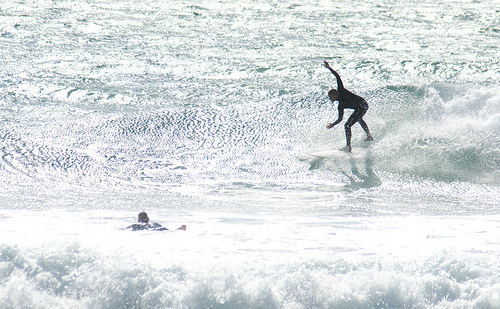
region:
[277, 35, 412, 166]
A person is surfing on water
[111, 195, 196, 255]
Another person is in the water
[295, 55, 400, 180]
Person is wearing a wetsuit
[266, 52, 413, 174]
Person's wetsuit is black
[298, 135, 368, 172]
Person's surfboard is white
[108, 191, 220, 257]
Person is laying flat on the water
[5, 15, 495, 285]
Picture was taken in the daytime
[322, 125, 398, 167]
Person on surfboard is barefoot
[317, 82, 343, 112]
Person on the surfboard has short hair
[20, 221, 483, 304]
The water is water in color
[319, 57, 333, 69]
the hand of a man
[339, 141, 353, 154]
the foot of a man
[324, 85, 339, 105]
the head of a man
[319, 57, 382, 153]
a man on a surfboard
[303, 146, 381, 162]
a white surfboard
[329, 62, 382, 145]
a black wet suit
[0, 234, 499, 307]
a foamy white wave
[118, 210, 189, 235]
a man lying on a surfboard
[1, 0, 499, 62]
calm water behind the surfers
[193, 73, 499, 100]
the crest of a wave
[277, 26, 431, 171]
a man surfing in the ocean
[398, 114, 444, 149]
water spraying into the air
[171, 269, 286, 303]
white waves rolling in the sea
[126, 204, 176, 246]
a man swimming in the ocean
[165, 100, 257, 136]
ripple in the ocean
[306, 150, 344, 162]
a white surfboard supporting a man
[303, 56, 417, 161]
a man with his arms raised in the air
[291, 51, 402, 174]
a surfer wearing a black wet suit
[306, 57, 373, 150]
a man falling off his surfboard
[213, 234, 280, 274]
light reflecting on the surface of the ocean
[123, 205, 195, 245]
A person lying flat in the water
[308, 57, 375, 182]
A person on a surfboard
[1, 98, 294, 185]
Dark ripple like patterns in the water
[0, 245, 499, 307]
White foamy area in the water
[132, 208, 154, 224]
A persons head sticking out of the water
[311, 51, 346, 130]
The surfer's arms out to the side while in bent position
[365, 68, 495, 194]
A rising wave in the water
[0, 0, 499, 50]
A white looking body of water with blue mingled in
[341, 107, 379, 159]
The surfer's legs balancing on the surfboard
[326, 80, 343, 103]
The head of the surfer standing in the water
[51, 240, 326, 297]
The wave is white.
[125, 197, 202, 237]
A surfer in the water.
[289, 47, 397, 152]
A man is surfing.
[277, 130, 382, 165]
The surfboard is white.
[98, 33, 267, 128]
The water is grey.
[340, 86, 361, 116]
The wetsuit is black.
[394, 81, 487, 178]
There is a wave behind the water.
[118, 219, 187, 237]
The man is lying on a surfboard.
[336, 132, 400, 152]
The surfer isn't wearing shoes.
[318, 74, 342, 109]
The surfer has a shaved head.